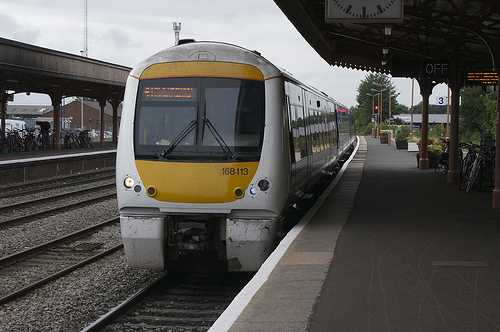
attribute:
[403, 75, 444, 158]
column — tan color, support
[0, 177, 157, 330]
gravel — gray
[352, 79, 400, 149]
street lights — tall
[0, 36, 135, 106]
canopy — large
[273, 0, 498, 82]
canopy — large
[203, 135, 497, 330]
platform — railway platform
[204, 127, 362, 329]
line — white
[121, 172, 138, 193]
headlight — on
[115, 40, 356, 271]
train — yellow, white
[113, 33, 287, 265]
front — yellow, black, gray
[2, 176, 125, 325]
tracks — train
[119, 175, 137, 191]
headlight — lit